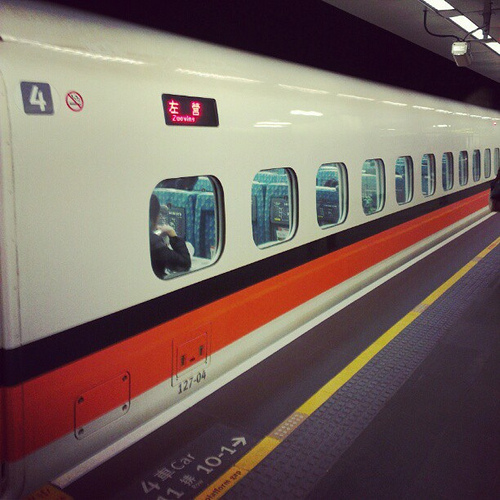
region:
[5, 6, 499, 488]
train is in a train station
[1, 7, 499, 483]
train is color white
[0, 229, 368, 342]
train has black and orange stripes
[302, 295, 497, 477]
a yellow line on a platform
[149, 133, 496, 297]
windows of a train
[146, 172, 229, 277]
a person can be seen inside a train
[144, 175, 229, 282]
a person wears a long sleeve top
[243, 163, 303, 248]
the sits of train can be seen through a window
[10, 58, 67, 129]
the number 4 on side the train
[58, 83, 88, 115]
a sign of smoke interdiction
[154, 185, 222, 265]
window on side of train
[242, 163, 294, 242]
window on side of train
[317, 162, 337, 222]
window on side of train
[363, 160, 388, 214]
window on side of train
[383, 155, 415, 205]
window on side of train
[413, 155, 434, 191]
window on side of train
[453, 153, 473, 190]
window on side of train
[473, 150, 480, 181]
window on side of train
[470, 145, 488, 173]
window on side of train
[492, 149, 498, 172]
window on side of train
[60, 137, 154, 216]
A train in the photo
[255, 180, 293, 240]
Glass panes on the window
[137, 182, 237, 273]
Window in the photo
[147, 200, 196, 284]
A person seated in the photo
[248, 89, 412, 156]
White train in the photo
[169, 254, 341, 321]
Red and black color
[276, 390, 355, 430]
Yellow mark on the side walk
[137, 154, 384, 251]
Windows on the train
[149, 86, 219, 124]
Signage on the train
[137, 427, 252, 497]
Text on the road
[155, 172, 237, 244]
window on the train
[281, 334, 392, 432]
yellow line on the ground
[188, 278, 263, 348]
orange line on train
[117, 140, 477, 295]
many windows on the train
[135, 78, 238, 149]
red lights on the train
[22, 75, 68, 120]
the number 4 on train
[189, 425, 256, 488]
numbers and an arrow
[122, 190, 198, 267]
person in the train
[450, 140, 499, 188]
windows in the background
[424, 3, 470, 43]
lights above the train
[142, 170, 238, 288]
A window on a train.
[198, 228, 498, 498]
A yellow line near a train.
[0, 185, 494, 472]
An orange line on a train.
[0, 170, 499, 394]
A black line on a train.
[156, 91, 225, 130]
A light on a train.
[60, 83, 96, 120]
a no smoking sticker.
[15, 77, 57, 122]
the number 4.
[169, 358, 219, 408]
a number on a train.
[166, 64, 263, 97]
a light reflecting on a train.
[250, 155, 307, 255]
a window on a train.